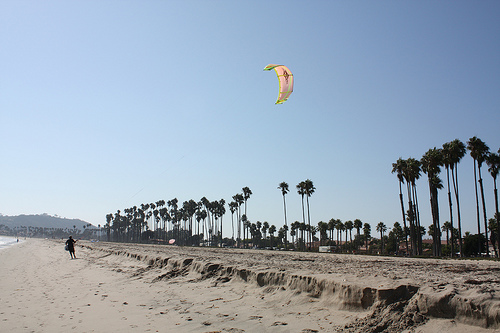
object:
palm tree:
[297, 180, 309, 245]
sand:
[49, 270, 186, 331]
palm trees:
[210, 201, 226, 239]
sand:
[236, 248, 397, 332]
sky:
[0, 1, 500, 244]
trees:
[105, 213, 115, 241]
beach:
[0, 237, 500, 333]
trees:
[152, 209, 159, 243]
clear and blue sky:
[352, 22, 436, 85]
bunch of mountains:
[0, 212, 98, 242]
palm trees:
[485, 152, 499, 225]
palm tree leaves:
[443, 143, 459, 163]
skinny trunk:
[282, 190, 289, 251]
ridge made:
[0, 137, 500, 261]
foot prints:
[24, 251, 97, 331]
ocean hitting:
[0, 233, 33, 258]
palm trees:
[228, 201, 240, 239]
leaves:
[235, 188, 253, 203]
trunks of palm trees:
[427, 222, 442, 256]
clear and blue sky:
[83, 22, 221, 99]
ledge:
[49, 238, 500, 332]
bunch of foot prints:
[93, 282, 315, 332]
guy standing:
[65, 235, 79, 260]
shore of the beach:
[0, 237, 499, 333]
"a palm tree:
[277, 182, 291, 250]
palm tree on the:
[440, 140, 468, 259]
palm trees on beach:
[183, 199, 198, 236]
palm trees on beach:
[155, 200, 167, 231]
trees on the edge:
[159, 207, 168, 243]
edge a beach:
[0, 230, 137, 333]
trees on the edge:
[353, 219, 362, 236]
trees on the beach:
[166, 198, 181, 238]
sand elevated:
[116, 245, 500, 331]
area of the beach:
[71, 252, 185, 332]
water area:
[0, 230, 25, 252]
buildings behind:
[316, 224, 338, 254]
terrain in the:
[0, 214, 92, 246]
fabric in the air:
[262, 63, 294, 105]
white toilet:
[319, 245, 337, 252]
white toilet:
[469, 252, 496, 258]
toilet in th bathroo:
[318, 245, 337, 253]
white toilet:
[456, 251, 462, 257]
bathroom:
[318, 238, 337, 253]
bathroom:
[150, 238, 178, 245]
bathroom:
[358, 237, 388, 254]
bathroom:
[396, 240, 432, 256]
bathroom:
[401, 239, 500, 255]